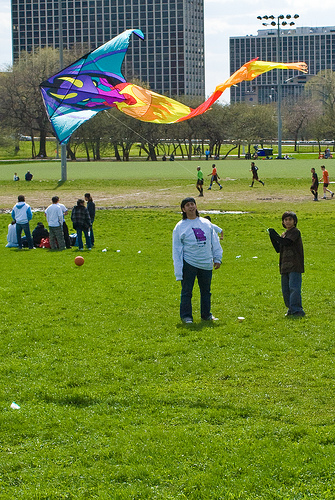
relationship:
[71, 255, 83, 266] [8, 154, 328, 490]
basketball rolling on ground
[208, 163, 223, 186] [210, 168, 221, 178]
man wearing orange tee shirt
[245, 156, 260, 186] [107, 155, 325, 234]
man running across field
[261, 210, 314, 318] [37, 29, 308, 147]
boy flying colorful kite flying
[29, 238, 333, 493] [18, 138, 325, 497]
grass in field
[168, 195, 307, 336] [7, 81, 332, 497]
people standing in park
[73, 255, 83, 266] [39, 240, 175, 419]
basketball in grass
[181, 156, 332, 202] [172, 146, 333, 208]
people playing soccer